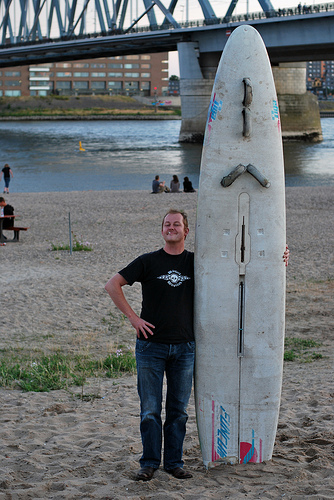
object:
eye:
[163, 222, 170, 227]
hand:
[129, 315, 156, 341]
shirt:
[119, 246, 196, 342]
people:
[182, 176, 196, 192]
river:
[0, 116, 334, 193]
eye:
[173, 222, 181, 226]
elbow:
[105, 280, 111, 298]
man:
[102, 203, 195, 484]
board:
[194, 22, 287, 466]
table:
[0, 219, 31, 244]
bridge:
[0, 0, 334, 68]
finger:
[139, 325, 148, 340]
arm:
[105, 256, 144, 324]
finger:
[286, 261, 290, 266]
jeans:
[133, 337, 195, 468]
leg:
[162, 357, 194, 470]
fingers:
[284, 257, 290, 262]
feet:
[161, 463, 194, 481]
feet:
[135, 464, 154, 483]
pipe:
[68, 212, 71, 256]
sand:
[0, 182, 334, 500]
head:
[161, 209, 188, 242]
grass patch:
[49, 240, 92, 250]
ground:
[0, 189, 334, 500]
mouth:
[165, 228, 177, 234]